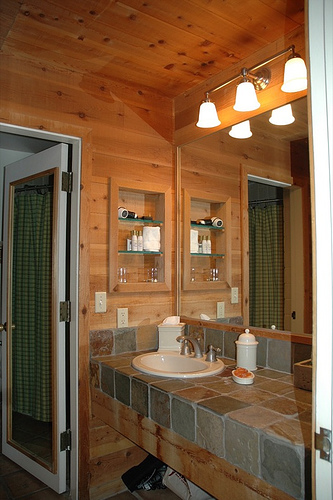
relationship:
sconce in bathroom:
[195, 44, 307, 130] [2, 1, 312, 500]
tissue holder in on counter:
[157, 321, 185, 351] [91, 347, 310, 448]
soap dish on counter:
[232, 365, 256, 387] [91, 347, 310, 448]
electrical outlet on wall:
[116, 306, 130, 330] [2, 59, 174, 499]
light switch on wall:
[94, 290, 108, 313] [2, 59, 174, 499]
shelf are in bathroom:
[117, 283, 164, 293] [2, 1, 312, 500]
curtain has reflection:
[12, 186, 54, 424] [247, 200, 288, 332]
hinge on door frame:
[60, 169, 75, 196] [1, 122, 85, 500]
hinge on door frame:
[58, 299, 73, 325] [1, 122, 85, 500]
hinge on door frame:
[60, 428, 73, 454] [1, 122, 85, 500]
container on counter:
[235, 329, 259, 374] [91, 347, 310, 448]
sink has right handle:
[131, 349, 224, 379] [204, 344, 223, 363]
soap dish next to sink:
[232, 365, 256, 387] [131, 349, 224, 379]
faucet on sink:
[176, 333, 202, 360] [131, 349, 224, 379]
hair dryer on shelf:
[116, 206, 139, 219] [116, 188, 164, 224]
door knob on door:
[2, 321, 16, 334] [3, 145, 68, 495]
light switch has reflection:
[94, 290, 108, 313] [229, 287, 240, 305]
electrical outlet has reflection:
[116, 306, 130, 330] [215, 300, 225, 321]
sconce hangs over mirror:
[195, 44, 307, 130] [175, 97, 312, 339]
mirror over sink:
[175, 97, 312, 339] [131, 349, 224, 379]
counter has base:
[91, 347, 310, 448] [89, 384, 297, 500]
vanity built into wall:
[92, 95, 310, 497] [173, 24, 309, 147]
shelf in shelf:
[116, 188, 164, 224] [117, 283, 164, 293]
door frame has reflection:
[1, 122, 85, 500] [240, 164, 291, 332]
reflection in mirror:
[240, 164, 291, 332] [175, 97, 312, 339]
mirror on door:
[8, 168, 57, 474] [3, 145, 68, 495]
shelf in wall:
[116, 188, 164, 224] [2, 59, 174, 499]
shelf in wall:
[116, 246, 163, 258] [2, 59, 174, 499]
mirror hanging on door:
[8, 168, 57, 474] [3, 145, 68, 495]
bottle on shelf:
[131, 229, 139, 253] [116, 246, 163, 258]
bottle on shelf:
[136, 230, 145, 252] [116, 246, 163, 258]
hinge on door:
[60, 169, 75, 196] [3, 145, 68, 495]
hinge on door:
[58, 299, 73, 325] [3, 145, 68, 495]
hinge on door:
[60, 428, 73, 454] [3, 145, 68, 495]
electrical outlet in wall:
[116, 306, 130, 330] [2, 59, 174, 499]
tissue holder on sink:
[157, 321, 185, 351] [131, 349, 224, 379]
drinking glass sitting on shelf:
[118, 267, 128, 286] [115, 262, 164, 289]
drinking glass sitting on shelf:
[149, 265, 161, 284] [115, 262, 164, 289]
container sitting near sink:
[235, 329, 259, 374] [131, 349, 224, 379]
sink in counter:
[131, 349, 224, 379] [91, 347, 310, 448]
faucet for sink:
[176, 333, 202, 360] [131, 349, 224, 379]